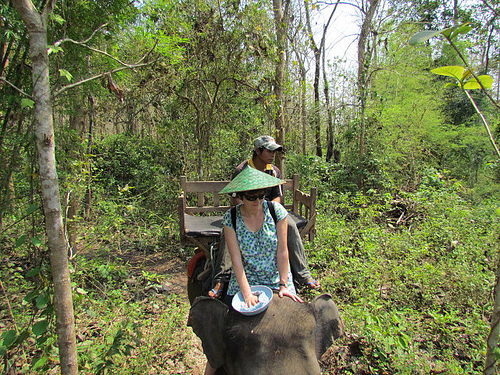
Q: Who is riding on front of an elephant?
A: A woman.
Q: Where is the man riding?
A: Behind the woman.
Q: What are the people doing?
A: Riding an elephant.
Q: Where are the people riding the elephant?
A: In the woods.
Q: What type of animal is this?
A: An elephant.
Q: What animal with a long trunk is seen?
A: Elephant.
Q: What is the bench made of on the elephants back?
A: Wood.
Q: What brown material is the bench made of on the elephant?
A: Wood.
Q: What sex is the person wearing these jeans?
A: Male.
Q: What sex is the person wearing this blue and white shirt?
A: Female.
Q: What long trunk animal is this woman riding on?
A: Elephant.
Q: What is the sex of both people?
A: Male and female.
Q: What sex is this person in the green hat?
A: Female.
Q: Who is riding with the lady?
A: The guide.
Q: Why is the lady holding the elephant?
A: To keep balance.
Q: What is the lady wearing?
A: A printed blue dress.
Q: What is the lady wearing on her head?
A: An Asian hat.